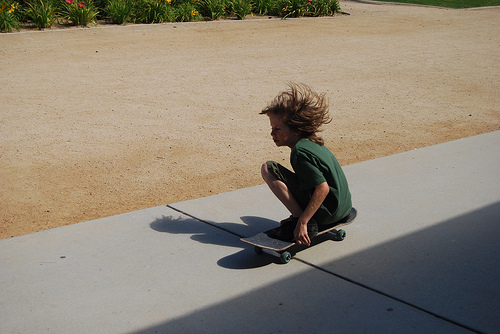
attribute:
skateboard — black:
[241, 201, 333, 251]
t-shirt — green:
[286, 117, 358, 242]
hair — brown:
[254, 90, 355, 157]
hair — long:
[174, 39, 361, 129]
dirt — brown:
[73, 33, 201, 167]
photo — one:
[67, 1, 449, 301]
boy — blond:
[202, 89, 361, 284]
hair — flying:
[259, 80, 330, 150]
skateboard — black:
[232, 215, 355, 264]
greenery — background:
[78, 6, 246, 90]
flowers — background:
[0, 0, 300, 55]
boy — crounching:
[205, 110, 342, 290]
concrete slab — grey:
[336, 160, 401, 305]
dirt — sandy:
[339, 52, 448, 118]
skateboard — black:
[216, 190, 376, 261]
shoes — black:
[279, 196, 339, 256]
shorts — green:
[265, 170, 335, 239]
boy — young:
[255, 85, 327, 280]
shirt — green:
[283, 132, 346, 229]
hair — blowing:
[243, 77, 347, 157]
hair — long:
[273, 69, 376, 156]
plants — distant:
[47, 0, 209, 30]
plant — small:
[11, 5, 57, 27]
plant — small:
[8, 8, 68, 24]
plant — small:
[48, 9, 109, 32]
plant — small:
[102, 0, 153, 18]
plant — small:
[124, 3, 172, 21]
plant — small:
[150, 0, 198, 42]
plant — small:
[116, 0, 213, 19]